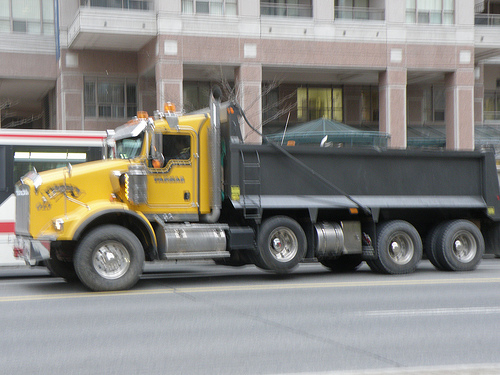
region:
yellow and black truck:
[56, 82, 498, 259]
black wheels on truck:
[210, 220, 492, 270]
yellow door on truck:
[139, 126, 207, 228]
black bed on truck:
[229, 128, 479, 214]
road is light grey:
[155, 310, 261, 370]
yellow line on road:
[2, 264, 369, 312]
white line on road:
[285, 287, 499, 368]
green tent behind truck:
[242, 107, 392, 152]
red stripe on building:
[0, 126, 119, 142]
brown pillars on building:
[158, 23, 467, 142]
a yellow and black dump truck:
[16, 105, 497, 279]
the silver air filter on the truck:
[118, 151, 161, 217]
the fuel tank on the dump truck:
[155, 222, 270, 274]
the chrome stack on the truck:
[193, 79, 233, 218]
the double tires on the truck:
[375, 209, 452, 298]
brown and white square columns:
[136, 53, 195, 117]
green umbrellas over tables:
[268, 99, 399, 162]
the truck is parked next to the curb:
[38, 105, 499, 293]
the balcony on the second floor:
[63, 12, 179, 53]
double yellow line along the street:
[13, 258, 488, 303]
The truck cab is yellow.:
[13, 100, 225, 282]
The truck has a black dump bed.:
[173, 83, 495, 215]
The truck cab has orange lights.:
[127, 101, 198, 120]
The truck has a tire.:
[64, 224, 156, 296]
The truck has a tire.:
[253, 214, 308, 275]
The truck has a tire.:
[373, 214, 422, 284]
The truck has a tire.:
[431, 212, 496, 280]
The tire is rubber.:
[68, 220, 145, 293]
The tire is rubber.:
[258, 217, 310, 272]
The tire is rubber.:
[374, 218, 425, 274]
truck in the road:
[14, 91, 498, 311]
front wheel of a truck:
[78, 226, 145, 293]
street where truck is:
[87, 301, 444, 368]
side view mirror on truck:
[138, 114, 170, 176]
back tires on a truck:
[369, 216, 493, 267]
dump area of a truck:
[231, 127, 498, 227]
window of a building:
[338, 3, 385, 36]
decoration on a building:
[384, 43, 407, 70]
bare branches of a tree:
[207, 69, 289, 134]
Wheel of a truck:
[245, 205, 339, 288]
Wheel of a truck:
[366, 210, 436, 293]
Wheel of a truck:
[436, 225, 495, 295]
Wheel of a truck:
[51, 212, 161, 297]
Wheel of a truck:
[252, 215, 309, 284]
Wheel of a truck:
[436, 215, 497, 280]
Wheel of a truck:
[252, 178, 309, 299]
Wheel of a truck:
[64, 191, 186, 331]